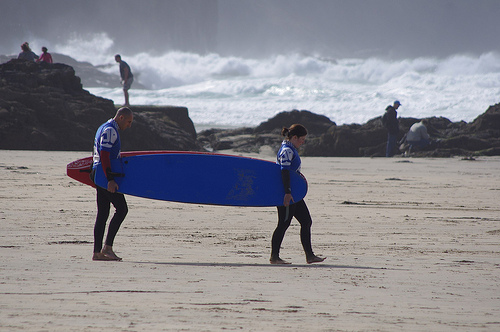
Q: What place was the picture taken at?
A: It was taken at the beach.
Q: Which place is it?
A: It is a beach.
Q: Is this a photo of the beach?
A: Yes, it is showing the beach.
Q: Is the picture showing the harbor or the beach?
A: It is showing the beach.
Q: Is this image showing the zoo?
A: No, the picture is showing the beach.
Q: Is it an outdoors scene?
A: Yes, it is outdoors.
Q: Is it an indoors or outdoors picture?
A: It is outdoors.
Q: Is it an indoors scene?
A: No, it is outdoors.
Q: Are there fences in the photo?
A: No, there are no fences.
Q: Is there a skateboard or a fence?
A: No, there are no fences or skateboards.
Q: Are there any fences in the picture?
A: No, there are no fences.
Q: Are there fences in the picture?
A: No, there are no fences.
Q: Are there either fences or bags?
A: No, there are no fences or bags.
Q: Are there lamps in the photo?
A: No, there are no lamps.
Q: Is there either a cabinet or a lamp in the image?
A: No, there are no lamps or cabinets.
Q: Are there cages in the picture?
A: No, there are no cages.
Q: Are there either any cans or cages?
A: No, there are no cages or cans.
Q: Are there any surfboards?
A: Yes, there is a surfboard.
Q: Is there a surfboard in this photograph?
A: Yes, there is a surfboard.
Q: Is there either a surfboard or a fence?
A: Yes, there is a surfboard.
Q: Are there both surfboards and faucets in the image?
A: No, there is a surfboard but no faucets.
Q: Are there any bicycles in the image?
A: No, there are no bicycles.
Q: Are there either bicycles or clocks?
A: No, there are no bicycles or clocks.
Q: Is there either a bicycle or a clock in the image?
A: No, there are no bicycles or clocks.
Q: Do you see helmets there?
A: No, there are no helmets.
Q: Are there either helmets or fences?
A: No, there are no helmets or fences.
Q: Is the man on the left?
A: Yes, the man is on the left of the image.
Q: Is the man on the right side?
A: No, the man is on the left of the image.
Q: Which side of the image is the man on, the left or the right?
A: The man is on the left of the image.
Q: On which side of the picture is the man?
A: The man is on the left of the image.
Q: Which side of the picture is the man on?
A: The man is on the left of the image.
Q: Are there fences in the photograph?
A: No, there are no fences.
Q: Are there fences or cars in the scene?
A: No, there are no fences or cars.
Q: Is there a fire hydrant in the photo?
A: No, there are no fire hydrants.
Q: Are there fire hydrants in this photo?
A: No, there are no fire hydrants.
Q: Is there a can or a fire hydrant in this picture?
A: No, there are no fire hydrants or cans.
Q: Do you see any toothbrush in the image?
A: No, there are no toothbrushes.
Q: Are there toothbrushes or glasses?
A: No, there are no toothbrushes or glasses.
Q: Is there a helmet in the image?
A: No, there are no helmets.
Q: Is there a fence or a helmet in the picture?
A: No, there are no helmets or fences.